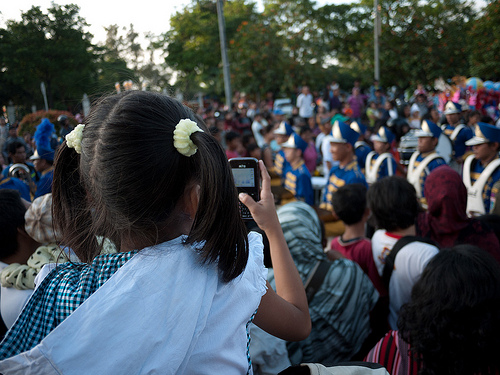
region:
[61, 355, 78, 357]
white fabric on shirt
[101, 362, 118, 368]
white fabric on shirt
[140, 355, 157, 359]
white fabric on shirt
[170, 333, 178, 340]
white fabric on shirt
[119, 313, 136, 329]
white fabric on shirt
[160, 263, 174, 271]
white fabric on shirt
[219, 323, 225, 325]
white fabric on shirt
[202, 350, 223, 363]
white fabric on shirt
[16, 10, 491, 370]
Photo taken during the day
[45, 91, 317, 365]
Little girl holding a cell phone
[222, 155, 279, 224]
Cell phone in the girl's hand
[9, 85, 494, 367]
People watching a parade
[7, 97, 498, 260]
Parade in the middle of the people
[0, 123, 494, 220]
Marching band wearing blue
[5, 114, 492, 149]
Hats on the marching band members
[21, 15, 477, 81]
Green leaves on the trees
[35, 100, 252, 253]
The girl's hair is in pigtails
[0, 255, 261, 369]
White shirt with a hood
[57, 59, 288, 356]
kid is holding a phone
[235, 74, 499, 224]
marching band in blue uniform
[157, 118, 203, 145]
white barette on hair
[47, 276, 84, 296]
green and blue plaid fabric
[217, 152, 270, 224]
black cell phone in girl's hand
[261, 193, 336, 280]
scarf on woman's head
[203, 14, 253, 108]
tall blue pole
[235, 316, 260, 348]
frilly end on white fabric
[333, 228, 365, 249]
brown and green collar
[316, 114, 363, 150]
blue and white military hat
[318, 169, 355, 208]
gold lines on blue shirt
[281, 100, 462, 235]
people watching marchers on the street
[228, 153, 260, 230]
a phone in the hand of a girl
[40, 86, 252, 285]
pig tails on a girls head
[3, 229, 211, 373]
a white hood with a checkered inside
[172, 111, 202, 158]
a yellow pony tail holder in a girl's hair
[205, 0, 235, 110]
a metal pole above the crowd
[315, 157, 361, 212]
a blue and gold shirt on a band member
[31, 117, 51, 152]
a blue feather on a hat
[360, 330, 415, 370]
a red, black, and white striped bag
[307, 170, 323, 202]
a white topped drum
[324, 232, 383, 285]
a red shirt with a black collar